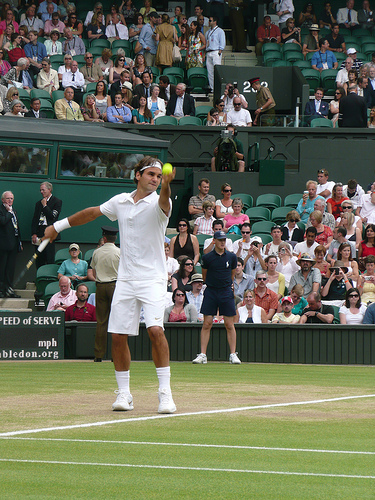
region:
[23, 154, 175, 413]
man playing tennis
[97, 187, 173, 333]
white outfit man is wearing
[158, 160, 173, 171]
yellow tennis ball in man's hand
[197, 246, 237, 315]
black outfit man is wearing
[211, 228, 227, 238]
black cap man is wearing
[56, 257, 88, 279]
green shirt man is wearing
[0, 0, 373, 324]
crowd of people watching the game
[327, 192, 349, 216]
red top woman is wearing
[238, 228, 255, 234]
black sunglasses man is wearing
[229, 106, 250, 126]
white shirt man is wearing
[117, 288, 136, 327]
white shorts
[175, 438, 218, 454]
a white line on the tennis court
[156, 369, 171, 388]
white socks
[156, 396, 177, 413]
a white shoe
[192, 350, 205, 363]
man is wearing white shoes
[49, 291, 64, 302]
man wearing a pink shirt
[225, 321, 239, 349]
leg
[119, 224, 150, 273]
man is wearing a white shirt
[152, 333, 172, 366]
the tennis players leg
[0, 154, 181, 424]
A man is playing tennis.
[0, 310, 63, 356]
A gray and white speed of serve sign.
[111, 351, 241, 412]
Four feet are in sneakers.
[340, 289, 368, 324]
A woman is wearing sunglasses.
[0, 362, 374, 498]
A tennis court is green.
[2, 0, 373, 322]
People are watching tennis.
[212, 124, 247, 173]
A man is behind a camera.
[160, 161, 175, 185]
A green ball is in a hand.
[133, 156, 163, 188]
A head is wearing a white headband.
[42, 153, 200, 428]
Tennis player wearing white shorts and shirt.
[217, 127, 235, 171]
Dark camera with green cloth on it.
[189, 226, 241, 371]
Man in blue shirt and shorts standing on the grass.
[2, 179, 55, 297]
Two men standing on steps wearing suit jackets.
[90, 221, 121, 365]
Man in uniform standing on grass while facing crowd.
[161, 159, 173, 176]
Light green tennis ball held by player.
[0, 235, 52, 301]
Tennis racket being swung by player.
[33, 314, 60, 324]
The word 'Serve' in white.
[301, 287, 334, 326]
Man wearing black shirt in first row.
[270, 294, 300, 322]
Man in red and white hat in the first row.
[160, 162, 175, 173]
a green tennis ball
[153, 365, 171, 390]
a man's white sock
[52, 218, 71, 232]
a white wristband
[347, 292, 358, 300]
dark black sunglasses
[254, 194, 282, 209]
a green stadium chair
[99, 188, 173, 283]
a man's white shirt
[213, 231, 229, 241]
a blue baseball cap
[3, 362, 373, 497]
part of a tennis court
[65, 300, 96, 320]
a man's red shirt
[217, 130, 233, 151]
a large gray video camera